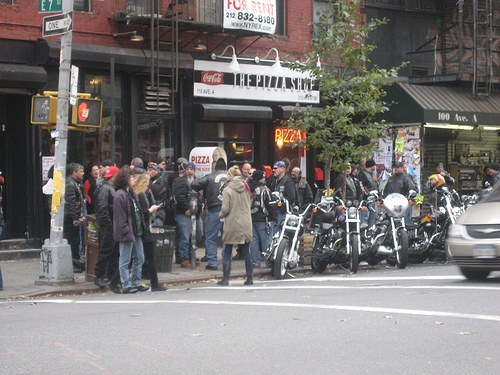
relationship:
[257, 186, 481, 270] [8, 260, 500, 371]
motorcycles are on road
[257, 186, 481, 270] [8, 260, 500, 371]
motorcycles are by road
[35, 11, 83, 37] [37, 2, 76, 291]
one way sign on a post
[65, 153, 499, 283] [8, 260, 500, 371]
people are on road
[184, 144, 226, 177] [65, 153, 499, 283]
pizza sign behind people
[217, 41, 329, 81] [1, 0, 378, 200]
lights are under building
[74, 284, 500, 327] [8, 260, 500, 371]
crosswalk on road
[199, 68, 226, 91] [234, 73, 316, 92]
coca cola logo on pizza shop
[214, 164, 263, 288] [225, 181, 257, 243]
woman wearing jacket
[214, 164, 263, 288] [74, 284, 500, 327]
woman on crosswalk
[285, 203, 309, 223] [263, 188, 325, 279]
windshield on motorcycle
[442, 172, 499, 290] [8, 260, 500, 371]
car on road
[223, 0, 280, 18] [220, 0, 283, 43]
for rent on sign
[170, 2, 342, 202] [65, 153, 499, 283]
pizza shop behind people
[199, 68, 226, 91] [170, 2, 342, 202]
coca cola logo on pizza shop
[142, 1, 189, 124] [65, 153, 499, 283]
fire escape ladder over people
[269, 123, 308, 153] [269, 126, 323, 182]
pizza sign in window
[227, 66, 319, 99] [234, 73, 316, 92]
pizza shop on pizza shop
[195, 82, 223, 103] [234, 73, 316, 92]
100 ave a on pizza shop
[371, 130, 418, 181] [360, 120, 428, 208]
informational papers are on board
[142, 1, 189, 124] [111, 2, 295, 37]
fire escape ladder on balcony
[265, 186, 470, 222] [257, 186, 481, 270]
handle bars are on motorcycles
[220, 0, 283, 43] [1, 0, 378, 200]
sign on building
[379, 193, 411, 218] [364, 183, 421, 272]
helmet on motorcycle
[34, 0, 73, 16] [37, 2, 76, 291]
street sign on post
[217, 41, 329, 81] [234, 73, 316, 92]
lights are over pizza shop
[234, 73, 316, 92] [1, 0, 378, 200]
pizza shop on building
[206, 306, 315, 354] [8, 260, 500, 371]
part of a road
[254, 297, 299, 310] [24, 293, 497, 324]
part of a line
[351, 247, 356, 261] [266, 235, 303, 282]
part of a wheel